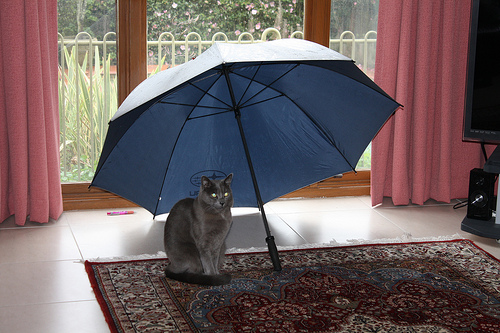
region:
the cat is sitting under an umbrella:
[86, 41, 414, 303]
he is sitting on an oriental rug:
[157, 180, 292, 330]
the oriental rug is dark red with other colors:
[258, 270, 468, 332]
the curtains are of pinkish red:
[391, 20, 476, 183]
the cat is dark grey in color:
[145, 171, 247, 285]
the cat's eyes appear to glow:
[191, 154, 239, 210]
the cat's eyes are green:
[196, 160, 242, 219]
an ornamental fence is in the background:
[51, 2, 381, 79]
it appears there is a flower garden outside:
[70, 45, 106, 154]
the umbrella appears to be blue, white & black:
[83, 14, 388, 219]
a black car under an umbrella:
[155, 161, 247, 286]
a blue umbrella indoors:
[83, 18, 414, 283]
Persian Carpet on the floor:
[67, 229, 499, 331]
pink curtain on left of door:
[3, 3, 73, 229]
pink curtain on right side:
[362, 7, 487, 216]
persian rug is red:
[71, 233, 498, 330]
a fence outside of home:
[55, 21, 127, 108]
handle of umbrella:
[239, 183, 294, 278]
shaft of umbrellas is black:
[241, 78, 278, 238]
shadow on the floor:
[3, 221, 75, 324]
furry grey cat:
[152, 165, 249, 291]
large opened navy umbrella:
[87, 30, 402, 276]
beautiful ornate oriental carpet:
[62, 226, 499, 331]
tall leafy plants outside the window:
[38, 36, 124, 189]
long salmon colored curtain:
[0, 0, 67, 237]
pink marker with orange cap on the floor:
[97, 207, 139, 222]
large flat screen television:
[457, 0, 499, 152]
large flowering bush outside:
[142, 0, 309, 62]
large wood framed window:
[35, 0, 378, 214]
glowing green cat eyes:
[205, 188, 235, 203]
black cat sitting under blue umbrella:
[100, 22, 417, 302]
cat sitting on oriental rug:
[157, 168, 242, 295]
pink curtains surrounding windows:
[362, 5, 472, 207]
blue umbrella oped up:
[104, 30, 403, 275]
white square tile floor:
[14, 213, 97, 321]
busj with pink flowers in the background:
[154, 1, 319, 39]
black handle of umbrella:
[234, 201, 309, 282]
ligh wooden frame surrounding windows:
[62, 6, 177, 213]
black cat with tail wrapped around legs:
[147, 168, 244, 290]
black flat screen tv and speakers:
[431, 28, 498, 248]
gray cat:
[153, 170, 240, 288]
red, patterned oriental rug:
[70, 234, 493, 331]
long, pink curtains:
[0, 0, 487, 219]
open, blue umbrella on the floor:
[78, 24, 407, 216]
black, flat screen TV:
[455, 0, 499, 167]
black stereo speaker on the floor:
[463, 167, 495, 222]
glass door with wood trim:
[21, 2, 385, 194]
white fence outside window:
[42, 23, 386, 149]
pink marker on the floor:
[104, 206, 138, 221]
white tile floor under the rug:
[1, 196, 498, 330]